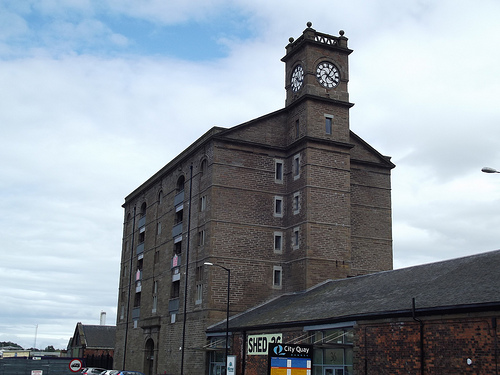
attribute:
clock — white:
[318, 57, 341, 90]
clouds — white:
[7, 4, 136, 54]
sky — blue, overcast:
[0, 1, 500, 346]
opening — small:
[275, 158, 286, 186]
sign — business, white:
[243, 331, 288, 357]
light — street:
[202, 261, 228, 274]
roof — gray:
[207, 248, 500, 334]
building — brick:
[109, 20, 397, 373]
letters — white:
[283, 344, 312, 355]